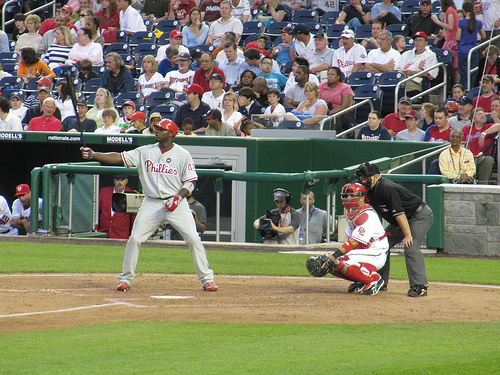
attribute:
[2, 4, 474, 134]
fans — watching the game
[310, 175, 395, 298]
man — squatting down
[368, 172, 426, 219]
shirt — black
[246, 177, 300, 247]
man — records game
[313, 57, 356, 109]
fan — sitting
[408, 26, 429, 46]
cap — red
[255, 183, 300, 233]
man — wearing earphones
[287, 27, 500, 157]
people looking — group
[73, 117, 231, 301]
team is phillies — man's, ball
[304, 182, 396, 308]
catchers helmet — red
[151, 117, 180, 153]
helmet is red — man's